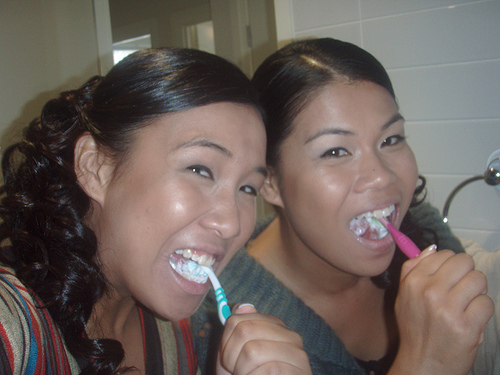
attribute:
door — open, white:
[196, 6, 260, 58]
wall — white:
[434, 86, 466, 132]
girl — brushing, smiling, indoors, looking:
[273, 42, 455, 344]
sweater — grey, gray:
[250, 268, 300, 308]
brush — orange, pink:
[388, 225, 427, 251]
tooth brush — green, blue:
[198, 276, 237, 315]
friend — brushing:
[70, 57, 263, 285]